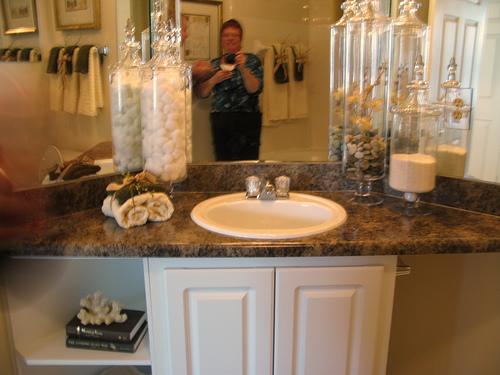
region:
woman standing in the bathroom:
[193, 15, 283, 161]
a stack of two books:
[54, 301, 146, 357]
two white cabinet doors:
[166, 267, 391, 374]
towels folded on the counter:
[98, 184, 180, 231]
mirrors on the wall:
[0, 0, 497, 205]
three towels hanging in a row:
[39, 39, 109, 122]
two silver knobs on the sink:
[233, 170, 303, 205]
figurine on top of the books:
[61, 288, 133, 328]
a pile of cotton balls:
[131, 63, 195, 185]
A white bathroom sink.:
[189, 174, 347, 241]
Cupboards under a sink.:
[139, 256, 400, 373]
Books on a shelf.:
[65, 302, 149, 354]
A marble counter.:
[5, 160, 499, 256]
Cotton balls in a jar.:
[138, 0, 189, 202]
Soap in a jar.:
[386, 55, 442, 222]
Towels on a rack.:
[48, 43, 107, 120]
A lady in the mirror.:
[192, 16, 265, 158]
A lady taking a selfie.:
[196, 18, 264, 160]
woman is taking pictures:
[195, 3, 283, 157]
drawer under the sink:
[280, 266, 420, 373]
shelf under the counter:
[10, 258, 150, 363]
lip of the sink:
[212, 220, 307, 242]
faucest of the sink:
[254, 176, 279, 200]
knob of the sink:
[269, 175, 294, 195]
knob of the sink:
[242, 170, 262, 200]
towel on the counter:
[92, 178, 174, 238]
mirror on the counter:
[285, 119, 322, 151]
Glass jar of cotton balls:
[137, 9, 195, 210]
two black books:
[62, 303, 149, 353]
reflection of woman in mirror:
[183, 5, 275, 166]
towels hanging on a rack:
[42, 39, 113, 124]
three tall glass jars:
[135, 1, 446, 223]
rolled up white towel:
[101, 185, 175, 229]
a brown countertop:
[10, 157, 497, 257]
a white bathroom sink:
[188, 170, 348, 245]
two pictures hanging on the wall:
[0, 0, 109, 40]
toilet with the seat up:
[25, 140, 84, 186]